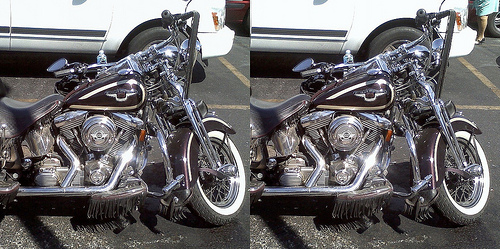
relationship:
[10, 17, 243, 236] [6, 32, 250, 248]
bike on top of pavement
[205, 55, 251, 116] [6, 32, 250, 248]
lines on pavement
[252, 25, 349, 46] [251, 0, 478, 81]
stripe on vehicle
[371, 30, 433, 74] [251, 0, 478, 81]
tire on vehicle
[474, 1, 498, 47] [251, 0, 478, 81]
woman in front of vehicle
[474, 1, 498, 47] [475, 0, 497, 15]
woman wearing skirt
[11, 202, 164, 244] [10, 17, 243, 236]
shadow cast from bike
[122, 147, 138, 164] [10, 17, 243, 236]
sunshine on bike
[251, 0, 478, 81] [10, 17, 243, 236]
vehicle next to bike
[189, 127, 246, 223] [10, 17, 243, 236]
tire on bike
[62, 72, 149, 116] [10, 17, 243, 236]
gas tank on bike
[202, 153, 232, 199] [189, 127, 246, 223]
forks on tire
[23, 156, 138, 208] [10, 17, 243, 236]
exhaust pipe on bike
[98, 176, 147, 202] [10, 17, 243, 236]
footboard on bike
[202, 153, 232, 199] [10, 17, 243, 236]
forks on bike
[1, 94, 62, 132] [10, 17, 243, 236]
seat on bike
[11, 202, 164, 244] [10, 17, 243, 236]
shadow cast by bike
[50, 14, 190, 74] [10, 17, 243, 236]
handle bars on bike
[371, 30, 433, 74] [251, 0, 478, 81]
tire of vehicle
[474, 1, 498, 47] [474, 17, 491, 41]
woman has leg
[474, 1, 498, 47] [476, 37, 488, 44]
woman wearing shoes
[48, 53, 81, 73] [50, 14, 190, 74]
mirror on handle bars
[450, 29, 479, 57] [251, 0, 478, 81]
bumper on vehicle